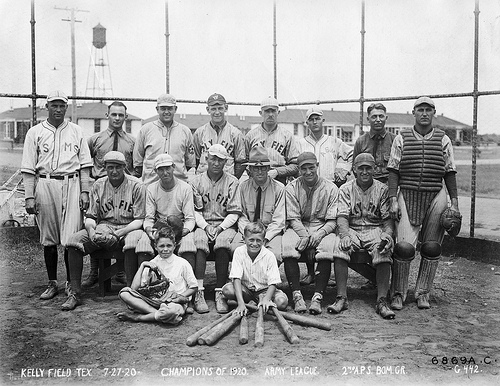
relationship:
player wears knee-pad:
[397, 98, 461, 310] [421, 240, 442, 261]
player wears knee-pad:
[397, 98, 461, 310] [389, 243, 417, 262]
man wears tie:
[239, 157, 285, 304] [254, 186, 261, 221]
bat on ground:
[249, 301, 332, 334] [4, 230, 499, 384]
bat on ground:
[268, 309, 303, 346] [4, 230, 499, 384]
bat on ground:
[257, 307, 264, 347] [4, 230, 499, 384]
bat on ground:
[238, 317, 250, 347] [4, 230, 499, 384]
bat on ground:
[205, 310, 238, 347] [4, 230, 499, 384]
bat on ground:
[200, 312, 233, 345] [4, 230, 499, 384]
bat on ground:
[185, 301, 233, 346] [4, 230, 499, 384]